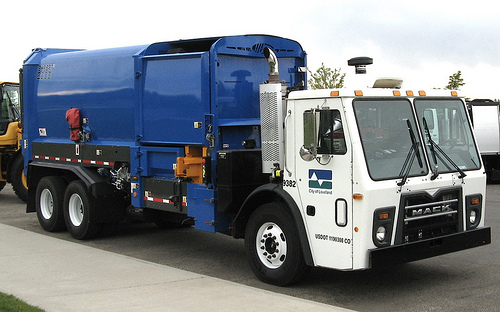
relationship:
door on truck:
[252, 96, 358, 250] [25, 49, 304, 238]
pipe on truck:
[257, 30, 301, 211] [25, 49, 304, 238]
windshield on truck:
[338, 85, 486, 146] [25, 49, 304, 238]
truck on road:
[25, 49, 304, 238] [15, 209, 254, 303]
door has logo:
[252, 96, 358, 250] [301, 174, 340, 203]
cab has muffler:
[294, 90, 482, 268] [257, 30, 301, 211]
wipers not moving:
[396, 116, 466, 187] [353, 88, 465, 181]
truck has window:
[25, 49, 304, 238] [353, 88, 465, 181]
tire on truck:
[245, 180, 303, 274] [25, 49, 304, 238]